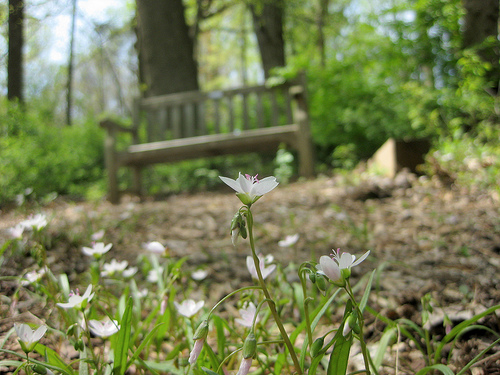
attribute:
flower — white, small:
[219, 173, 304, 375]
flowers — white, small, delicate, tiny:
[2, 172, 372, 374]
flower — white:
[317, 249, 372, 375]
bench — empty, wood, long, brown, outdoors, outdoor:
[97, 70, 312, 204]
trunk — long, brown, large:
[133, 2, 204, 136]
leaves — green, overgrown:
[2, 97, 109, 208]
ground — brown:
[4, 185, 499, 315]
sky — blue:
[2, 2, 137, 123]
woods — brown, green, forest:
[1, 1, 498, 133]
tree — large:
[247, 2, 286, 81]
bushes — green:
[285, 11, 499, 162]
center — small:
[243, 173, 260, 185]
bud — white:
[230, 213, 247, 248]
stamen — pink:
[66, 289, 82, 303]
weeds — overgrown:
[413, 116, 499, 203]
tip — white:
[230, 226, 240, 251]